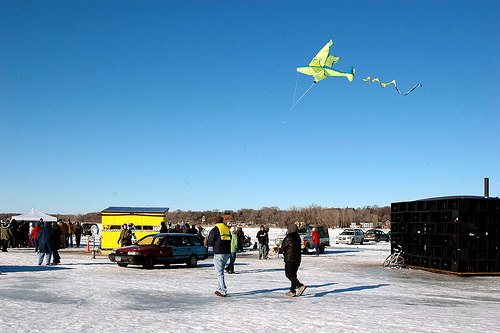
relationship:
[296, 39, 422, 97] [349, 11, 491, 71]
kite flying in sky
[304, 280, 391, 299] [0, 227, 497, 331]
shadow on ground